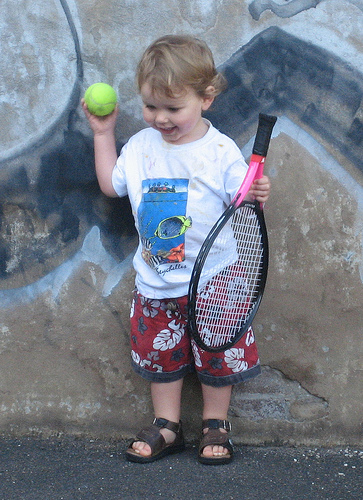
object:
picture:
[139, 176, 190, 274]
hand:
[250, 176, 270, 204]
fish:
[151, 216, 192, 240]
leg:
[141, 294, 185, 426]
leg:
[189, 302, 239, 431]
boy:
[79, 32, 270, 465]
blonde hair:
[134, 34, 226, 95]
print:
[128, 262, 261, 382]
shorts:
[126, 256, 261, 389]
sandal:
[124, 417, 183, 463]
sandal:
[197, 419, 233, 464]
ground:
[1, 440, 360, 498]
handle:
[252, 112, 277, 157]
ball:
[85, 83, 117, 116]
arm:
[92, 114, 127, 199]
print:
[130, 168, 191, 285]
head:
[134, 35, 215, 142]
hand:
[81, 94, 119, 132]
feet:
[130, 416, 182, 455]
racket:
[187, 114, 269, 354]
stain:
[97, 105, 104, 112]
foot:
[200, 423, 229, 456]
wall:
[1, 1, 350, 449]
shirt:
[111, 119, 250, 298]